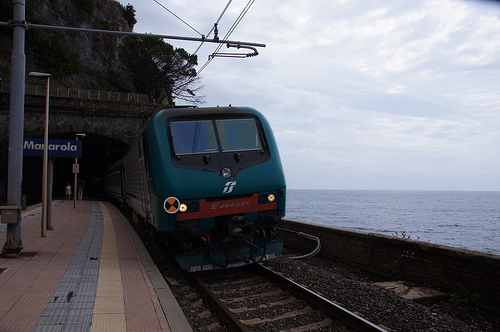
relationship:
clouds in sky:
[113, 0, 499, 191] [132, 1, 499, 195]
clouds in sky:
[374, 90, 474, 182] [272, 23, 483, 237]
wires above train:
[142, 6, 273, 77] [143, 109, 283, 229]